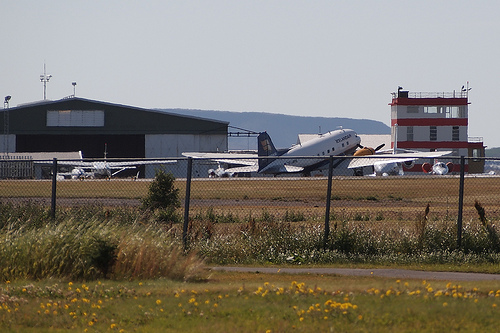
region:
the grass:
[237, 267, 307, 328]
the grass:
[262, 281, 302, 312]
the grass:
[254, 297, 272, 305]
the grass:
[279, 282, 309, 302]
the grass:
[214, 269, 278, 322]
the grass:
[257, 296, 313, 323]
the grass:
[214, 244, 331, 326]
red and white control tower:
[379, 77, 498, 148]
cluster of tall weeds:
[11, 212, 218, 297]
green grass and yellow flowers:
[8, 274, 478, 328]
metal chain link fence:
[0, 147, 497, 249]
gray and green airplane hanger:
[1, 93, 241, 180]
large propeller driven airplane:
[136, 97, 468, 197]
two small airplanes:
[26, 146, 191, 186]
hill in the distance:
[142, 99, 397, 160]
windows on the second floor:
[37, 102, 116, 131]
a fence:
[65, 111, 468, 320]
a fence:
[146, 180, 398, 317]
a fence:
[205, 181, 347, 276]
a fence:
[141, 205, 288, 307]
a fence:
[260, 233, 352, 290]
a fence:
[181, 159, 293, 326]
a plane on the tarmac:
[178, 122, 460, 182]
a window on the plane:
[343, 136, 352, 149]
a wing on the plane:
[323, 139, 464, 174]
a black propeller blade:
[373, 138, 388, 153]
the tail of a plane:
[248, 124, 288, 171]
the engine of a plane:
[348, 135, 390, 157]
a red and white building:
[386, 82, 488, 167]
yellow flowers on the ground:
[286, 293, 363, 326]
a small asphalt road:
[208, 256, 498, 288]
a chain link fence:
[1, 150, 497, 265]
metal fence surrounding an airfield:
[2, 147, 499, 259]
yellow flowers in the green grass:
[2, 265, 498, 332]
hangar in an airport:
[0, 85, 240, 188]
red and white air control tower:
[385, 78, 475, 178]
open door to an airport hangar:
[8, 124, 150, 188]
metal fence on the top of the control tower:
[389, 88, 467, 98]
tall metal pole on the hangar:
[36, 56, 53, 103]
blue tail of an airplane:
[250, 121, 279, 171]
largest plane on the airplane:
[178, 121, 459, 184]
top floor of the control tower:
[388, 100, 468, 121]